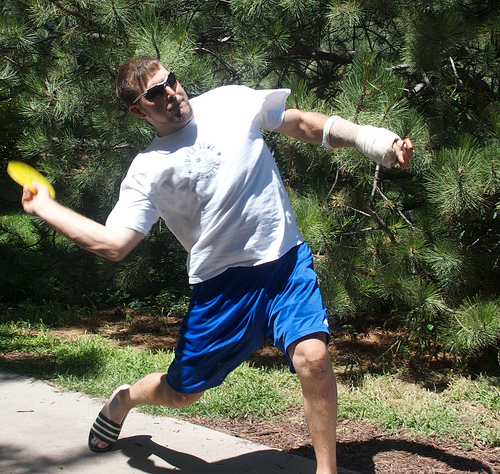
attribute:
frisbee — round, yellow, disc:
[2, 150, 60, 199]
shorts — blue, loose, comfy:
[174, 271, 334, 342]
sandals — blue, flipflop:
[78, 407, 131, 458]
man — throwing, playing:
[88, 50, 387, 473]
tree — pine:
[341, 29, 460, 86]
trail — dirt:
[93, 318, 152, 347]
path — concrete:
[23, 393, 59, 464]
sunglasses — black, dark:
[138, 74, 189, 99]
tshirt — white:
[157, 146, 288, 251]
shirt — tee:
[210, 96, 263, 217]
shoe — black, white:
[92, 440, 103, 452]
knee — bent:
[168, 392, 199, 411]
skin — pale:
[94, 233, 119, 265]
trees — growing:
[40, 32, 80, 110]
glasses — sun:
[157, 77, 178, 88]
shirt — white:
[183, 216, 252, 237]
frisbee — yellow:
[8, 158, 29, 172]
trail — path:
[383, 347, 434, 407]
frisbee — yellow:
[40, 177, 52, 187]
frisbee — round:
[16, 177, 22, 183]